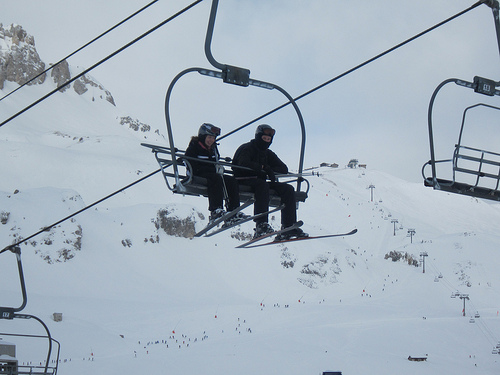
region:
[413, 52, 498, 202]
Empty ski lift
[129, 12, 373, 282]
Two skiers sitting on ski lift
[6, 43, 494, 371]
Blanket of snow covering the ground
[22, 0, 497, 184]
Completely cloud covered sky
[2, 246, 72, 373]
One of two empty ski lifts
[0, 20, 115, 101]
Rocky top of mountains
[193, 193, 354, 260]
Two sets of skiis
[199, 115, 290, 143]
Two winter hats on heads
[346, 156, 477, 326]
Power poles going up the mountain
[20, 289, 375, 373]
Areas where there is no snow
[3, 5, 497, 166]
light in daytime sky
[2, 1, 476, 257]
suspended cables of ski lift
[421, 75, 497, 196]
empty ski lift chair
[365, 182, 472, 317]
lights on side of mountain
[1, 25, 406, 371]
rocky snow covered mountain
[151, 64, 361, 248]
two people on ski lift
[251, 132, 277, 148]
ski mask over face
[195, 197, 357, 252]
two sets of skis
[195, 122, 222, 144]
helmet on skier's head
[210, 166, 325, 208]
two sets of ski poles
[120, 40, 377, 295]
People on a ski lift.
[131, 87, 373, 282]
Two people on the ski lift.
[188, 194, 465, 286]
Skis on the skiers.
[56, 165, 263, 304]
Snow on the mountain.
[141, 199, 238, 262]
Rock showing through the snow.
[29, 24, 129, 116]
Lines on the ski lift.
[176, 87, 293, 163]
Helmets on the skiers.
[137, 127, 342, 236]
Bench on the ski lift.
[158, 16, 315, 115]
Connector to the ski lift.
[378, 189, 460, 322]
Trees on the mountain.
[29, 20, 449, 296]
people on a ski lift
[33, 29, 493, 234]
two ski lifts in the shot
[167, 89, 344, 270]
a couple about to go skiing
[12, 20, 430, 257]
a snow covered mountain behind the skiers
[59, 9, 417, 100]
cloudy skies above the skiers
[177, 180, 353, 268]
the skiers legs are dangling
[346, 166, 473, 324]
parts of the ski lift system along the mountain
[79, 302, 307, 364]
the little dots in the snow are people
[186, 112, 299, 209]
they are wearing black ski coats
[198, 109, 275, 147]
they both have on goggles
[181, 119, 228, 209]
Woman on ski lift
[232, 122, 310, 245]
Man sitting on ski lift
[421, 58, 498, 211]
Empty ski life chair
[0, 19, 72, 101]
Large rocks in the background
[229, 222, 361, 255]
Man wearing skis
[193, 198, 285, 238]
Woman wearing skis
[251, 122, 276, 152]
Man wearing wool mask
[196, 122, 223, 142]
Woman wearing hat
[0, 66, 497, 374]
Snow all over the ground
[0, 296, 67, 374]
Empty chair on ski lift